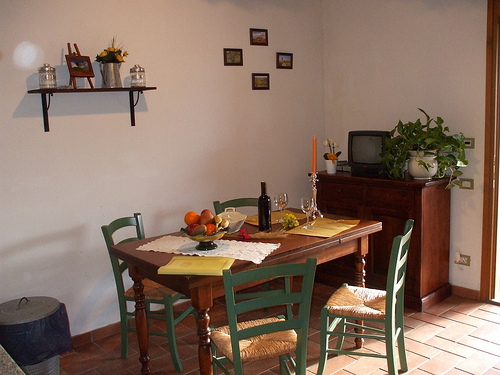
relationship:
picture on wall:
[221, 47, 244, 67] [120, 149, 183, 187]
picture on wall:
[274, 52, 296, 70] [48, 175, 87, 205]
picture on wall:
[274, 52, 296, 70] [182, 69, 220, 114]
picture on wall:
[249, 24, 279, 49] [146, 142, 195, 174]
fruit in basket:
[185, 230, 218, 246] [182, 212, 221, 233]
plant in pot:
[376, 107, 469, 191] [407, 150, 441, 182]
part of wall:
[326, 0, 482, 86] [320, 0, 487, 297]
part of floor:
[404, 291, 497, 372] [64, 294, 498, 373]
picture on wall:
[248, 27, 270, 47] [2, 1, 324, 351]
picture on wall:
[221, 49, 244, 66] [2, 1, 324, 351]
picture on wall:
[276, 52, 296, 68] [2, 1, 324, 351]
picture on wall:
[253, 72, 270, 91] [2, 1, 324, 351]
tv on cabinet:
[344, 130, 391, 179] [307, 171, 451, 315]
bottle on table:
[253, 179, 273, 229] [109, 205, 382, 373]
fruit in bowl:
[183, 211, 201, 224] [181, 229, 229, 248]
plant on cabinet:
[376, 107, 469, 191] [307, 171, 451, 315]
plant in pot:
[379, 107, 469, 191] [407, 143, 441, 181]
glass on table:
[300, 198, 313, 230] [109, 205, 382, 373]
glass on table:
[272, 189, 289, 230] [109, 205, 382, 373]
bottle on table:
[257, 181, 274, 235] [109, 205, 382, 373]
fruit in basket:
[186, 206, 231, 236] [176, 224, 228, 251]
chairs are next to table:
[100, 171, 427, 364] [122, 188, 379, 288]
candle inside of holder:
[298, 130, 324, 180] [302, 175, 323, 217]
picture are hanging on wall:
[251, 72, 271, 91] [2, 1, 324, 351]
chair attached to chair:
[314, 219, 416, 375] [324, 220, 416, 370]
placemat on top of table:
[287, 215, 363, 245] [126, 200, 366, 366]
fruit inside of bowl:
[185, 205, 235, 234] [185, 207, 247, 239]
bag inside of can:
[5, 314, 63, 356] [0, 286, 75, 373]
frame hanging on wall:
[250, 17, 271, 46] [3, 0, 313, 280]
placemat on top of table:
[160, 253, 244, 288] [126, 200, 366, 366]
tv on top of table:
[339, 115, 409, 179] [321, 161, 452, 297]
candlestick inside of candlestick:
[306, 130, 329, 180] [302, 171, 325, 221]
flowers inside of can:
[101, 44, 124, 63] [95, 60, 125, 90]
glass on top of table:
[297, 198, 313, 230] [122, 193, 379, 364]